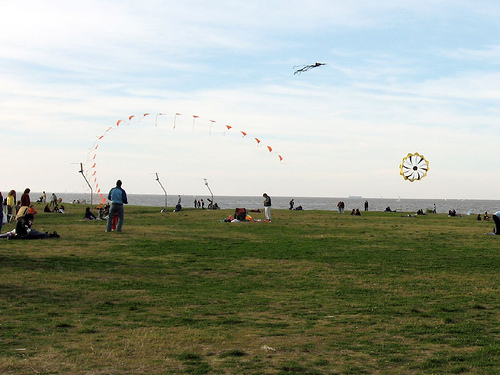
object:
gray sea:
[0, 192, 500, 215]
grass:
[0, 200, 500, 375]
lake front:
[0, 202, 499, 375]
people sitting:
[15, 212, 60, 240]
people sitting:
[83, 207, 102, 221]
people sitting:
[386, 206, 397, 212]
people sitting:
[354, 208, 361, 216]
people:
[363, 200, 369, 211]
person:
[261, 192, 273, 223]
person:
[19, 187, 30, 206]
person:
[193, 199, 197, 208]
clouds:
[150, 58, 192, 76]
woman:
[6, 189, 16, 223]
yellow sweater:
[7, 194, 14, 206]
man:
[105, 180, 128, 234]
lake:
[0, 191, 500, 216]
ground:
[0, 203, 500, 375]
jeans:
[106, 203, 124, 232]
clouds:
[442, 133, 498, 159]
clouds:
[461, 110, 499, 159]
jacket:
[108, 186, 129, 205]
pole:
[204, 180, 214, 209]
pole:
[156, 174, 168, 207]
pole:
[78, 163, 94, 210]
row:
[79, 161, 213, 207]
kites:
[278, 154, 283, 161]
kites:
[267, 146, 273, 153]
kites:
[254, 137, 262, 148]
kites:
[239, 131, 247, 138]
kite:
[398, 151, 430, 182]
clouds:
[0, 0, 53, 26]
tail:
[172, 115, 178, 130]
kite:
[292, 61, 328, 77]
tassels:
[222, 129, 229, 137]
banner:
[92, 110, 284, 205]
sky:
[0, 0, 500, 201]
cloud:
[131, 85, 156, 98]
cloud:
[157, 155, 177, 170]